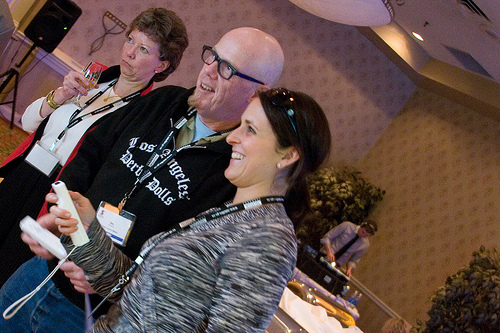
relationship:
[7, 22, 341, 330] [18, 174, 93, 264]
they holding controllers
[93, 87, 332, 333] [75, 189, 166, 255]
woman have on badges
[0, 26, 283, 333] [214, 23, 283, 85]
man without hair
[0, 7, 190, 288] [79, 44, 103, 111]
woman holding wine glass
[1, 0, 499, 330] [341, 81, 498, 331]
wallpaper on walls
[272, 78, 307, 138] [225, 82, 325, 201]
sunglasses on head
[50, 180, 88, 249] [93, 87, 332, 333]
wii mote in woman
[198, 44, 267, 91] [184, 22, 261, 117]
black glasses on face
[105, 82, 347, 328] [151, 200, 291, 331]
woman wearing shirt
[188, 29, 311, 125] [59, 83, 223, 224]
man wearing shirt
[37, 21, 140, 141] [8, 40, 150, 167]
woman wearing shirt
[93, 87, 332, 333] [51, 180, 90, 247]
woman holding controllers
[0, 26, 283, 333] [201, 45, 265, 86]
man wearing black glasses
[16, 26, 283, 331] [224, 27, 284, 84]
man has bald head